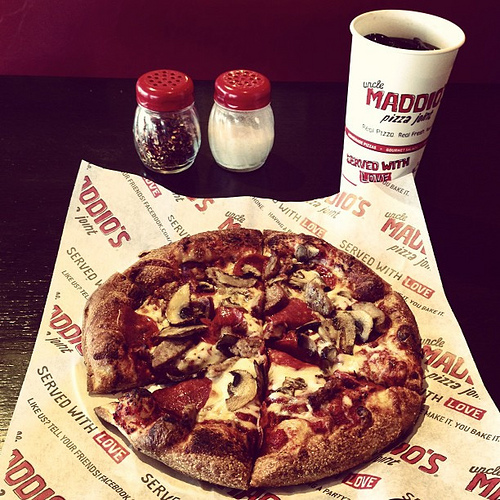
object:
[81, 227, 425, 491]
pizza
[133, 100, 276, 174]
glass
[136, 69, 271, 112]
caps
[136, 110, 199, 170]
pepper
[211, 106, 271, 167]
salt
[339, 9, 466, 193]
cup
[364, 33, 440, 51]
soda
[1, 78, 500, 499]
table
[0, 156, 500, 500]
paper